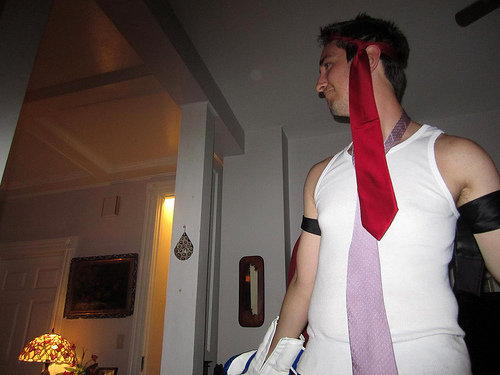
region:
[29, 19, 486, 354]
Picture is taken indoors.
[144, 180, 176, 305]
A light is on in the room.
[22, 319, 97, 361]
The desk lamp is on.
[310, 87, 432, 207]
The man is wearing a tie around his neck.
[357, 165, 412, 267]
The tie is red.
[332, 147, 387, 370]
The man is wearing a purple tie.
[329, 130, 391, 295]
The purple tie is around his neck.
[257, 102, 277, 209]
The wall is white.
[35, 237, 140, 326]
A painting is on the wall.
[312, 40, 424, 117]
The man is smiling.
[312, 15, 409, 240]
the boy has a red tie tied around his forehead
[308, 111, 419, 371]
the boy has a lavender tie around his neck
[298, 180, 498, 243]
the boy is wearing black arm bands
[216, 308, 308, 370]
the arm has a untied boxing glove on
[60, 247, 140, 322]
a framed picture is on the wall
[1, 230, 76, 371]
a closed white door is in the room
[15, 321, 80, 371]
a lit lamp light has a multicolored shade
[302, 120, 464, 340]
the man is wearing a white t-shirt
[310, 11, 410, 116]
the man has dark short hair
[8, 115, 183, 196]
the cantilevered ceiling is beige with a white trim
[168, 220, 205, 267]
black and gold hanging on wall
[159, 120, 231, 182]
white edge on the wall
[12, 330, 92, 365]
beautiful tiffany lamp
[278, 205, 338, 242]
broad black band on man's arm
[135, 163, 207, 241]
bright line in the room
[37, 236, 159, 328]
large black shiny painting on the wall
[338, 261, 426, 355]
purple tie around man's neck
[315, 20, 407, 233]
red tie around man's head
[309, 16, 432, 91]
man's short black hair cut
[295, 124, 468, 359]
man wearing white tee shirt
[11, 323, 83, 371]
yellow and red illuminated glass lampshade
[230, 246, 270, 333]
mirror with wooden frame hanging on a wall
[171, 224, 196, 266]
teardrop shaped tan and black spotted wall hanging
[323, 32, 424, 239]
red tie worn as a headband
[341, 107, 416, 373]
purple necktie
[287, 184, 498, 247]
black armbands wrapped around a man's biceps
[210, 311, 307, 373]
white glove worn on a man's right hand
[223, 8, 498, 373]
man with short dark hair wearing a silly outfit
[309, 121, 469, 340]
white tank top shirt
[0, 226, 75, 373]
white door with a white door frame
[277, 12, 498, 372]
man wearing multiple ties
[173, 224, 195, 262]
spotted wall decoration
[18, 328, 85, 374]
lit tiffany lamp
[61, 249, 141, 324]
art hanging from the wall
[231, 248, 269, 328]
object with brownish borders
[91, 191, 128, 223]
white square object attached to the wall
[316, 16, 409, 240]
red tie hanging from man's head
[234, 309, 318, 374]
white and blue gloves on the man's hand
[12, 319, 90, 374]
one lamp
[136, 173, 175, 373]
entrance of a room